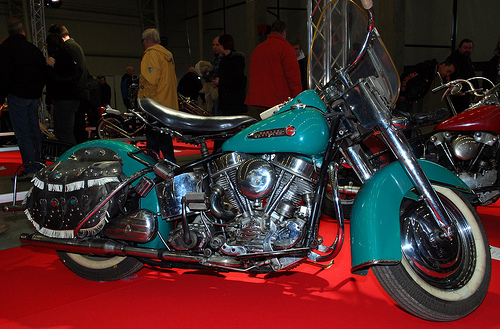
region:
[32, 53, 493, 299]
a motorcycle on display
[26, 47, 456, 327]
a motorcycle on display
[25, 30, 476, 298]
a motorcycle on display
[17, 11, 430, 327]
a motorcycle on display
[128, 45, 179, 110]
the jacket is yellow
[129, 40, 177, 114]
the jacket is yellow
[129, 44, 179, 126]
the jacket is yellow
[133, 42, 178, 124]
the jacket is yellow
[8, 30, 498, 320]
large turquoise motorcycle on display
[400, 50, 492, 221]
large red motorcycle on display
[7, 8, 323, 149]
men standing behind motorcycle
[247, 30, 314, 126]
man wearing an orange jacket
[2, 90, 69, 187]
man wearing blue jeans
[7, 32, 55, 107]
man wearing black top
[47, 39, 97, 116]
man wearing black top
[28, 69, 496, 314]
two motorcycles on display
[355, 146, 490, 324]
front wheel of motorcycle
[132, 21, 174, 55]
the hair of a man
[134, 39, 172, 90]
the arm of a man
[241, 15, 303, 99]
the back of a man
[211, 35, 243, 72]
the neck of a man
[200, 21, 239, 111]
the eyes of a man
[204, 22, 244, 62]
the nose of a man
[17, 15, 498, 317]
Green motorcycle on display.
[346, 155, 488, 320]
Front tire of motorcycle.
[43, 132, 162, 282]
Back tire of motorcycle.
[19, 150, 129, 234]
Black saddle bag on rear of bike.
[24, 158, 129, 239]
Black saddle bag with white fringe.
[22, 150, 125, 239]
Black saddle with decorative studs.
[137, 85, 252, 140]
Black molded motorcycle seat.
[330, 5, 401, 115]
Windshield on front of motorcycle.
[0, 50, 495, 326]
Motorcycle parked on red carpet.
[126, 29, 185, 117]
A person wearing a yellow jacket.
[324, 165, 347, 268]
metal chrome piece of motorcycle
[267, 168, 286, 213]
metal chrome piece of motorcycle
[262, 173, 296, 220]
metal chrome piece of motorcycle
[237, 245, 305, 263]
metal chrome piece of motorcycle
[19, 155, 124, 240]
the saddle bag is black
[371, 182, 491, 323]
the front tire is black and white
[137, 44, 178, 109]
the jacket is yellow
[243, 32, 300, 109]
the jacket is red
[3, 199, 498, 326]
the carpet is red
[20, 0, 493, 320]
the saddlebag on the motorcycle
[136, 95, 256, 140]
the seat is black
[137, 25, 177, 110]
the man is wearing a jacket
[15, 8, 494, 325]
A motorcycle on display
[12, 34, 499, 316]
An aqua colored motorcycle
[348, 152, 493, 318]
The front wheel of the motorcycle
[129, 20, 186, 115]
A woman wearing a yellow rain jacket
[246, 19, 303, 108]
A man wearing an orange jacket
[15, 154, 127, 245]
A saddlebag on the motorcycle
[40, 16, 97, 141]
A person looking at the display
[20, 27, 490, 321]
A motorcycle on a red carpet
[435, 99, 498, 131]
A motorcycle gas tank painted red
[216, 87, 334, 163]
An aqua colored gas tank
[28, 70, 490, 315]
an old blue and black motorcycle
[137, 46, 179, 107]
a large yellow jacket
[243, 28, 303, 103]
a red jacket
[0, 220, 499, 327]
a red carpet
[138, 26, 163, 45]
short cut gray hair